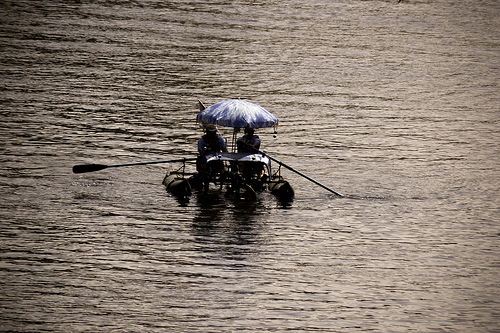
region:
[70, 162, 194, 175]
an oar hanging off the side of a boat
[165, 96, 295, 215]
a boat made out of floating cylinders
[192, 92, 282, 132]
umbrella over the people on the boat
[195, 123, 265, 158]
two people on a boat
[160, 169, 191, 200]
floating cylinder holding up a boat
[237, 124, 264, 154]
person holding the oar on the right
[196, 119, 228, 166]
person holding the oar on the left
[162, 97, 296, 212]
a floating vessel on the water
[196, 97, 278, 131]
a cover to shade the people on the boat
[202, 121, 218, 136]
a hat on the man's head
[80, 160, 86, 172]
the paddle is wooden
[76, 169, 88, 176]
the paddle is wooden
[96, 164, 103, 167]
the paddle is wooden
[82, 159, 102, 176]
the paddle is wooden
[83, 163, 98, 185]
the paddle is wooden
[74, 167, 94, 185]
the paddle is wooden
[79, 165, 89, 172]
the paddle is wooden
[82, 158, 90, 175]
the paddle is wooden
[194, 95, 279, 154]
a blue umbrella is shading two men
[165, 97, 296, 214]
the umbrella is on a raft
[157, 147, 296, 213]
the make shift raft is on barrels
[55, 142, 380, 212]
long oars are being used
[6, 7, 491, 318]
the water is gray and has ripples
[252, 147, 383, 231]
one oar is in the water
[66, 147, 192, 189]
one oar is out of the water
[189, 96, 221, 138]
a buoy is in the water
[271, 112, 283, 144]
balls are hanging from the umbrella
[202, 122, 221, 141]
the man has a helmet on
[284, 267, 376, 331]
The water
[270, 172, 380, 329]
The water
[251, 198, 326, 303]
The water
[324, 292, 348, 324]
The water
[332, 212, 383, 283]
The water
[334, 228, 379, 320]
The water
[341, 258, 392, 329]
The water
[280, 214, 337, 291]
The water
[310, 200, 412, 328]
The water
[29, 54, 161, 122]
the water is dark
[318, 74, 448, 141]
the water is still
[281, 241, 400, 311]
the water is calm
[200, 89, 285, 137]
the umbrella is big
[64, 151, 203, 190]
the ore is long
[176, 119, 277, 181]
the people are rowing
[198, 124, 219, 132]
the person is wearing a hat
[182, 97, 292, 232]
the people are on the water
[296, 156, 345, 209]
the ore is in the water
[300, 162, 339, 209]
the oar is at an angle